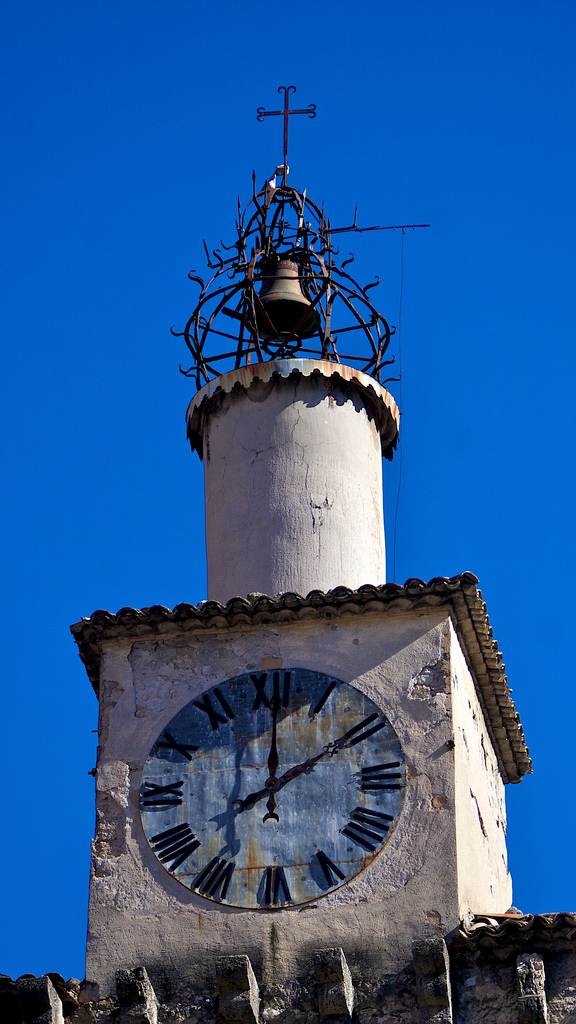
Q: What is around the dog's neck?
A: A collar.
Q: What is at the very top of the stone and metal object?
A: A cross.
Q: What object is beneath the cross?
A: A bell.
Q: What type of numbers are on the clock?
A: Roman numerals.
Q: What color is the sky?
A: Blue.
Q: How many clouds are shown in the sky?
A: None.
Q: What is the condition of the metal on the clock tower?
A: Rusted.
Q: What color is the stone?
A: Gray.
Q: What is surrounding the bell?
A: Iron.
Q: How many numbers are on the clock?
A: 12.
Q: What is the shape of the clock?
A: Circle.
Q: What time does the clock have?
A: 2:00.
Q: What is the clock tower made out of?
A: Stone.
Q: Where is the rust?
A: On the clock face.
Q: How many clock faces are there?
A: One.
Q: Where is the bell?
A: On top of the clock tower.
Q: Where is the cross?
A: On top of the bell.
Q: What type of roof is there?
A: A tile roof.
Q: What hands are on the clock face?
A: Hour and minute hands.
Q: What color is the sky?
A: Blue.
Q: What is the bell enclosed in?
A: Metal structure.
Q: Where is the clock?
A: On tower.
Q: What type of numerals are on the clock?
A: Roman numerals.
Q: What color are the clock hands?
A: Black.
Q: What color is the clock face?
A: White.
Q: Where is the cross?
A: On top of the metal structure.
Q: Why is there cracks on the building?
A: Erosion.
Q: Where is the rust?
A: On clock face.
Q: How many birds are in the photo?
A: No birds.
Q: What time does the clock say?
A: 2pm.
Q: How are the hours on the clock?
A: Roman numerals.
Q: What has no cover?
A: The clock.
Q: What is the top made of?
A: Metal.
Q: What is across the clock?
A: A shadow.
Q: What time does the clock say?
A: 12:10.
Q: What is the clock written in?
A: Roman numerals.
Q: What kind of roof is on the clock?
A: Tile.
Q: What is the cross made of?
A: Metal.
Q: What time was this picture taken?
A: 2:00.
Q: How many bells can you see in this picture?
A: 1.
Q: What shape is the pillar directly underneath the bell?
A: Cylinder.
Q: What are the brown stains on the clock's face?
A: Rust.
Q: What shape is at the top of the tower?
A: Cross.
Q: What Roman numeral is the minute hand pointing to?
A: XII.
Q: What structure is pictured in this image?
A: An old clock tower.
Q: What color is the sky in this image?
A: Blue.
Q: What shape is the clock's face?
A: Circle.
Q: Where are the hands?
A: On the clock.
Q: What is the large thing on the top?
A: On the tower.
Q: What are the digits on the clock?
A: Roman numerals.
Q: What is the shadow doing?
A: Falling across the top of the clock.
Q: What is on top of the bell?
A: Sharp twisted metal.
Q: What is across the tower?
A: A shadow.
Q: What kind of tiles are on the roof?
A: Grooved tiles.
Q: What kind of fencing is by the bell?
A: Iron.